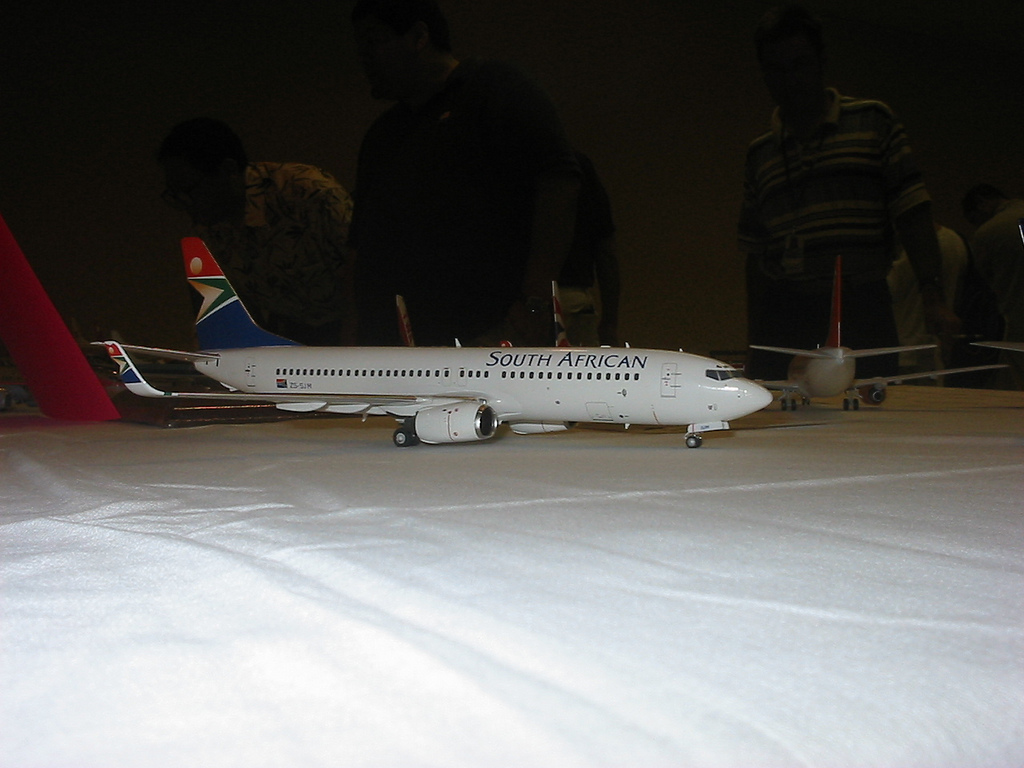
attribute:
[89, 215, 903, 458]
plane — south african, toy, red, white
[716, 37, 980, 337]
man — walking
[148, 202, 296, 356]
tail — red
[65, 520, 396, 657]
cloth — white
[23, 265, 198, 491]
sign — red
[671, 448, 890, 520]
pavement — gray